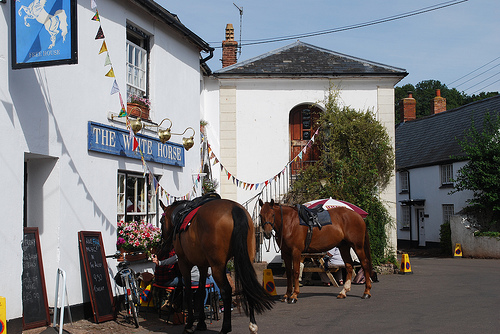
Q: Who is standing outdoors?
A: Horses.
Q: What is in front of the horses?
A: A building.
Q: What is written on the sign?
A: The White Horse.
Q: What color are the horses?
A: Brown.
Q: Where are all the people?
A: No where.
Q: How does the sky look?
A: Clear.